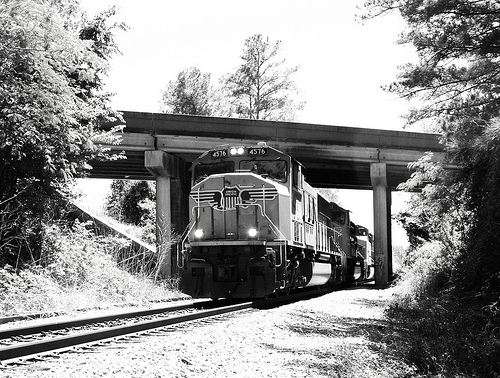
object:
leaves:
[0, 0, 130, 191]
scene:
[0, 1, 497, 376]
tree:
[0, 0, 128, 275]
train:
[176, 141, 375, 301]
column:
[370, 166, 392, 283]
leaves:
[391, 192, 469, 251]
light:
[237, 145, 245, 157]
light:
[227, 147, 240, 157]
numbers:
[249, 147, 266, 154]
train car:
[175, 140, 353, 296]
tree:
[361, 0, 500, 366]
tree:
[158, 65, 220, 115]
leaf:
[407, 161, 411, 165]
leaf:
[411, 162, 414, 166]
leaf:
[419, 156, 424, 160]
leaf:
[421, 185, 426, 190]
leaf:
[430, 191, 437, 196]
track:
[0, 293, 340, 370]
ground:
[1, 205, 419, 377]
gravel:
[155, 342, 199, 361]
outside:
[2, 3, 498, 375]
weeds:
[7, 229, 171, 312]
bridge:
[0, 108, 468, 292]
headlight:
[247, 225, 258, 237]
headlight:
[192, 227, 204, 239]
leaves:
[187, 90, 197, 105]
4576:
[211, 148, 227, 157]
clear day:
[5, 7, 499, 360]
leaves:
[391, 259, 453, 326]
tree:
[221, 33, 299, 122]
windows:
[194, 156, 286, 186]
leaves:
[227, 35, 258, 95]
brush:
[34, 224, 176, 307]